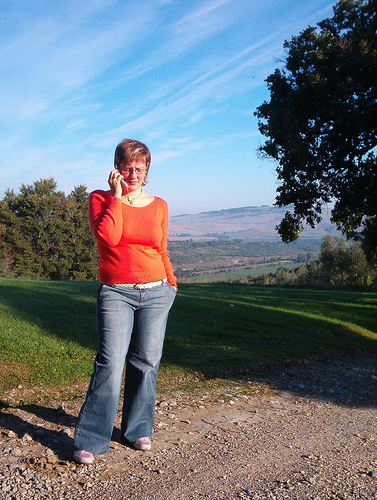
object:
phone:
[113, 166, 130, 193]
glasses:
[118, 164, 146, 178]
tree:
[252, 1, 377, 247]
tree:
[1, 173, 72, 281]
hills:
[168, 204, 319, 238]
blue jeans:
[73, 282, 178, 454]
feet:
[72, 443, 97, 463]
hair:
[114, 138, 153, 191]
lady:
[65, 136, 184, 462]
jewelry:
[119, 192, 141, 205]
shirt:
[86, 188, 177, 293]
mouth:
[126, 178, 140, 185]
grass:
[0, 275, 377, 405]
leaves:
[272, 198, 277, 210]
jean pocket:
[165, 282, 179, 308]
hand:
[168, 274, 179, 296]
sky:
[1, 1, 377, 220]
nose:
[131, 170, 140, 180]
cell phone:
[109, 169, 128, 192]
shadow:
[0, 277, 377, 414]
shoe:
[71, 443, 94, 466]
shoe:
[135, 437, 153, 452]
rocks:
[157, 467, 166, 477]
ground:
[1, 284, 377, 499]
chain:
[121, 193, 140, 210]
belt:
[111, 277, 170, 289]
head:
[114, 137, 151, 189]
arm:
[88, 189, 123, 251]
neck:
[117, 188, 147, 197]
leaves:
[20, 212, 23, 221]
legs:
[76, 284, 132, 447]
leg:
[118, 292, 172, 439]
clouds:
[101, 1, 256, 95]